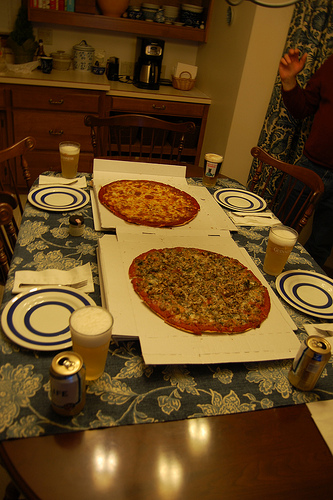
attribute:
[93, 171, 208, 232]
pizza — cheese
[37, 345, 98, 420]
can — open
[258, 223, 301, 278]
beer — in glass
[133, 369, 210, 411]
cloth — table cloth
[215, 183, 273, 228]
plate — empty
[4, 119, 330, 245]
chairs — wooden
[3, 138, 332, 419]
table — blue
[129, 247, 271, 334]
pizza — whole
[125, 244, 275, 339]
pizza — big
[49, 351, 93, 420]
can — shiny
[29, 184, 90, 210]
plate — empty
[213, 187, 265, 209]
plate — empty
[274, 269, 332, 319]
plate — empty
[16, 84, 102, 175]
drawers — closed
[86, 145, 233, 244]
pizza — whole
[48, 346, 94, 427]
can — gold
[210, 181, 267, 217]
plate — round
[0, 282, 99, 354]
plate — empty, blue, white, round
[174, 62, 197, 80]
paper — tissue paper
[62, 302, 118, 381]
glass — clear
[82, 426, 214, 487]
lamps — reflection